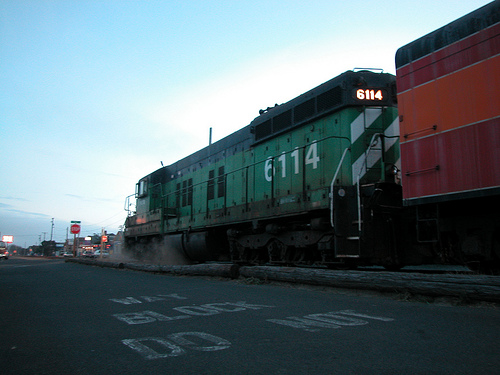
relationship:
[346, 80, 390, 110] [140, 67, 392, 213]
number on train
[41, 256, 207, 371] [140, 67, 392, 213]
road near train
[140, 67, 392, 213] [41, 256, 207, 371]
train above road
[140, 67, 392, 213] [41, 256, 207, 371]
train on road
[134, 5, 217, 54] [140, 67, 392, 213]
sky above train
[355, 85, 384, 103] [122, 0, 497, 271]
numbers on train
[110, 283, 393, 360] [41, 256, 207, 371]
paint on road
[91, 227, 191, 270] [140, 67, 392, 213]
smoke coming from train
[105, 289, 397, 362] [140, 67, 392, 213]
letters on a train